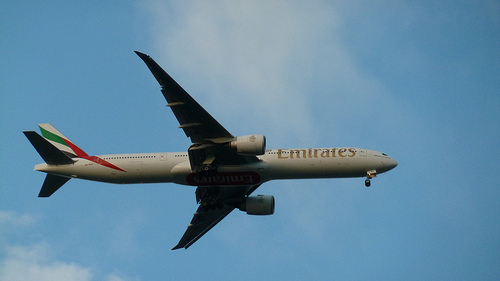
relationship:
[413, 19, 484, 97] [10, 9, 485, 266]
portion of sky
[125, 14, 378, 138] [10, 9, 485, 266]
clouds in sky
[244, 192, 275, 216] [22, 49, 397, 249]
engine on or side of plane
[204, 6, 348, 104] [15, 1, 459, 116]
white clouds in background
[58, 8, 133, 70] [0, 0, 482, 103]
blue sky in background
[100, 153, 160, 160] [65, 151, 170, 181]
passenger windows in main fuselage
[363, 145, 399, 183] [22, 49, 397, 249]
front part of a plane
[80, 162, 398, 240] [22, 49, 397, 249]
bottom part of a plane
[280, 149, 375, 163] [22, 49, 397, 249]
side part of a plane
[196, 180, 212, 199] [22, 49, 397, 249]
back wheels of a plane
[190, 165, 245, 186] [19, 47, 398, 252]
section of a flying plane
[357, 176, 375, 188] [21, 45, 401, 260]
wheels on an airplane